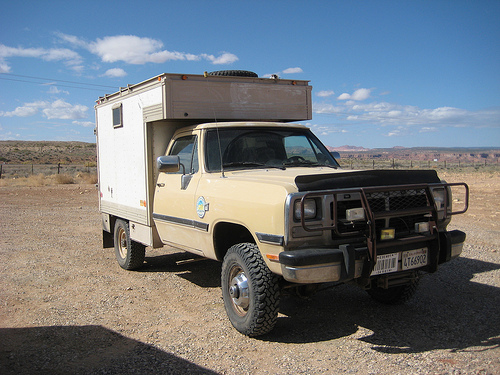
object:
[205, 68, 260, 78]
tire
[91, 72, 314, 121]
roof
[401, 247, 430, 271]
license plate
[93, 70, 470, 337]
cab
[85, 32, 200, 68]
cloud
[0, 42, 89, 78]
cloud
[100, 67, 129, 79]
cloud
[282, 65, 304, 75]
cloud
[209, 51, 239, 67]
cloud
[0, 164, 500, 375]
ground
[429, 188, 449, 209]
headlights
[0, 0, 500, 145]
sky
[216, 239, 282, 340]
tire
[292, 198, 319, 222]
headlight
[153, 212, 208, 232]
black stripe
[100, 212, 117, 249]
mud flap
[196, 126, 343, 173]
shield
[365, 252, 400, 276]
plates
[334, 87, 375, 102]
clouds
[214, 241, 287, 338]
front tire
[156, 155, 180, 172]
mirror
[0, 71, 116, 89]
electrical lines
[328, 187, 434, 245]
grill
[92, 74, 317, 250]
cargo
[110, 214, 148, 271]
tire